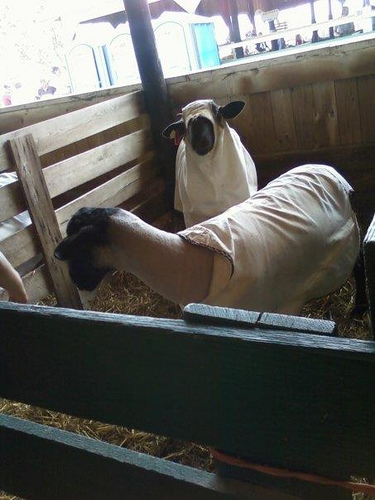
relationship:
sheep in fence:
[162, 93, 257, 228] [0, 86, 181, 302]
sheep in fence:
[162, 93, 257, 228] [0, 300, 373, 498]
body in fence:
[54, 162, 370, 316] [0, 86, 181, 302]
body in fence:
[54, 162, 370, 316] [0, 300, 373, 498]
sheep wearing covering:
[162, 93, 257, 228] [182, 163, 359, 313]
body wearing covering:
[54, 162, 370, 316] [176, 99, 257, 228]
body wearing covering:
[54, 162, 370, 316] [169, 140, 368, 313]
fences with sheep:
[4, 36, 361, 491] [175, 109, 272, 219]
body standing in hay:
[54, 162, 370, 316] [16, 216, 363, 477]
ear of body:
[45, 221, 100, 268] [54, 162, 370, 316]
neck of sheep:
[119, 198, 228, 298] [128, 53, 283, 215]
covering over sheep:
[173, 99, 257, 228] [152, 92, 257, 228]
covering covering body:
[179, 163, 361, 313] [54, 162, 370, 316]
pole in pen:
[123, 0, 180, 208] [3, 33, 373, 498]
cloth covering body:
[261, 221, 324, 262] [159, 162, 356, 320]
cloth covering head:
[187, 102, 215, 114] [157, 92, 249, 156]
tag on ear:
[170, 128, 183, 142] [210, 92, 234, 122]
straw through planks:
[0, 398, 213, 472] [0, 301, 374, 498]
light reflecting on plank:
[9, 411, 227, 490] [0, 415, 266, 498]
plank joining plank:
[260, 70, 302, 146] [247, 83, 299, 166]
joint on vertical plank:
[249, 308, 268, 340] [259, 309, 337, 339]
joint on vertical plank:
[249, 308, 268, 340] [182, 302, 260, 328]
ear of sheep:
[216, 96, 245, 119] [162, 93, 257, 228]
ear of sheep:
[160, 113, 188, 139] [162, 93, 257, 228]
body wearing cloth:
[54, 162, 370, 316] [170, 159, 365, 313]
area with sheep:
[5, 36, 363, 495] [162, 93, 257, 228]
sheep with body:
[162, 93, 257, 228] [54, 162, 370, 316]